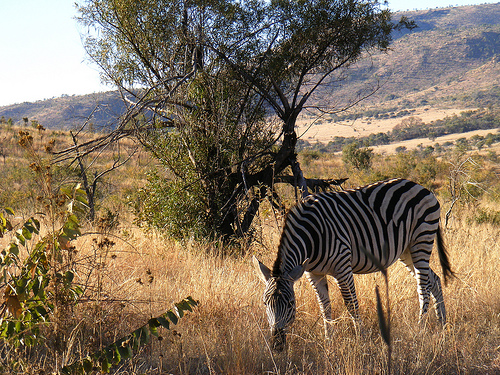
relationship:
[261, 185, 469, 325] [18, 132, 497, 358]
zebra in field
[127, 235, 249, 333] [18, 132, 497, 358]
grass in field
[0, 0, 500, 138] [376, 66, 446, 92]
background covered in rocks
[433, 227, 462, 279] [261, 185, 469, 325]
tail of zebra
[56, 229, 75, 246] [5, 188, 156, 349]
leaves of bush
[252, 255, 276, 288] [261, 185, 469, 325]
ear of zebra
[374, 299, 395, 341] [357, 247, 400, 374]
buds on buds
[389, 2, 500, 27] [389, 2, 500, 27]
ridge on ridge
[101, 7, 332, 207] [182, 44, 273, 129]
trees with leaves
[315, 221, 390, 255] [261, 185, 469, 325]
stripes on zebra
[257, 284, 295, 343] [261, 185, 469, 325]
head of zebra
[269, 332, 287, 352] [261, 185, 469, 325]
mouth of zebra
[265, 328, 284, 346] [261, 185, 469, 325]
nose of zebra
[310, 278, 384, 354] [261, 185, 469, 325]
front legs of zebra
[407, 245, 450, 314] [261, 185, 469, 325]
back legs of zebra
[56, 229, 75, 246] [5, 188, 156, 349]
leaves on bush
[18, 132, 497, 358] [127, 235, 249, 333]
field with grass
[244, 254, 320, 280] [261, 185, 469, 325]
ears of zebra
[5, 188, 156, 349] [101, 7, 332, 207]
bush beside trees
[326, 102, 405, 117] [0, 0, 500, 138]
trees on background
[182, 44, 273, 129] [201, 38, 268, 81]
leaves on branch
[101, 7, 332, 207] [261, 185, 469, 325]
trees behind zebra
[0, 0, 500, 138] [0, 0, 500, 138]
background in background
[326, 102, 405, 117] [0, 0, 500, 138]
trees in background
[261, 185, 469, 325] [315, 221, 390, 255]
zebra has stripes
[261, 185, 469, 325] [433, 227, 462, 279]
zebra has tail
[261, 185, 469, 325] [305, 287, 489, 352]
zebra has legs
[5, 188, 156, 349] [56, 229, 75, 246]
bush with leaves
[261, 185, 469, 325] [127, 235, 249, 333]
zebra in grass